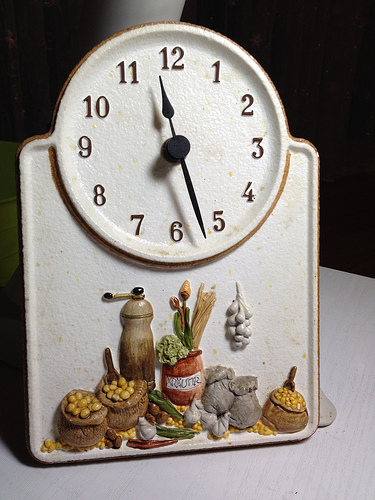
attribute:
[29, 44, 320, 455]
clock — white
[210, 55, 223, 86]
digit — 1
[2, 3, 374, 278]
form — white, in darkness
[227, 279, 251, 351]
garlic — twisted stalks, white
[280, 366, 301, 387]
spoon — measuring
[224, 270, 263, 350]
design — garlic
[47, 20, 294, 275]
clock — round, analog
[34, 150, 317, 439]
surface — white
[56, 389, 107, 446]
bag — potatoes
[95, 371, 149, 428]
bag — potatoes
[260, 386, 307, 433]
bag — potatoes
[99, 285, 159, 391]
pepper grinder — large, gray, brown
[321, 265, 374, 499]
table — flat, white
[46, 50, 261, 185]
clock — analog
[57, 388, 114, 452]
bag — image , potatoes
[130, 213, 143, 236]
digit — 7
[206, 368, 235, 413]
sack — burlap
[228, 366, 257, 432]
sack — burlap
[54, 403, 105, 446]
bag — open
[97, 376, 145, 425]
bag — open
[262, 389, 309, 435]
bag — open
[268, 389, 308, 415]
food — yellow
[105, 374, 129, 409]
food — yellow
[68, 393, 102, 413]
food — yellow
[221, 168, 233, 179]
speck — yellow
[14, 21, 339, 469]
clock — pictured, ceramic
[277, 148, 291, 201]
trim — brown